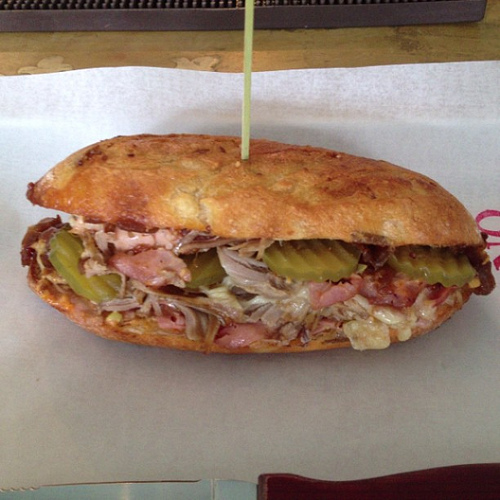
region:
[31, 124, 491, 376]
an amazing looking sandwich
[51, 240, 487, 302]
pickles are in the sandwich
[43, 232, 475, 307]
the pickles are green in color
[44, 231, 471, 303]
the pickles have crinkles in them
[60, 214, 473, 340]
meat is in the sandwich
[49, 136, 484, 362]
the bread is a golden brown color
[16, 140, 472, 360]
the bread looks toasted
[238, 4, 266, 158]
a stick in the bread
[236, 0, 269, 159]
the stick is small and skinny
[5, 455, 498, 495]
a knife near the sandwich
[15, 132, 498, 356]
a sandwich filled with meat.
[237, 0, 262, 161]
a stick sticking out of a sandwich.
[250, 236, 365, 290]
a pickle on a sandwich.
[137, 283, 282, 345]
onion on a sandwich.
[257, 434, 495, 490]
A brown wooden knife handle.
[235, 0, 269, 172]
A tooth pick in a sandwich.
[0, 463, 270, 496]
A sharp blade on a knife.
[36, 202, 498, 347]
meaty filling in a sandwich.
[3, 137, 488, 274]
the top of a sandwich.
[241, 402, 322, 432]
a section of a counter top.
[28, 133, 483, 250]
toasted bun on sandwich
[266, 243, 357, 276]
green pickle in sandwich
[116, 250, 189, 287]
cooked ham in sandwich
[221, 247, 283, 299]
pulled pork in sandwich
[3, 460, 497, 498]
wood and metal knife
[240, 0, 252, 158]
green pick in sandwich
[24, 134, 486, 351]
toasted cuban sandwich on paper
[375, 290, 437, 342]
melted cheese in sandwich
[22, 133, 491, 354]
toasted sandwich on paper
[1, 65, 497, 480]
white wax food paper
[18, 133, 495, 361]
Cold sub on a white sheet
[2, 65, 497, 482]
White sheet used to hold the sub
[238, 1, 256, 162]
Thin stick used to hold the contents of the sub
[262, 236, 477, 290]
Couple of pickles in the sub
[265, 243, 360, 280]
Pickle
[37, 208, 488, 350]
Group of cold cut meats and cheese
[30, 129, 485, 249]
Top layer of the toasted bread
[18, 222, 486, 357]
Bottom layer of the toasted bread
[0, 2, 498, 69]
Table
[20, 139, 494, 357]
Sub lying on a table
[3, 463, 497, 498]
Silver and wood knife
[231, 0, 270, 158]
Skinny mint green toothpick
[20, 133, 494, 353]
Sandwitch with pork, ham, cheese and pickles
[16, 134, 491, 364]
Lightly toasted sandwitch bun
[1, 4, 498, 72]
Light brown table with water stains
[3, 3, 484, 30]
Dark brown mat with bristles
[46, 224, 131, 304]
Circular, thin pickle slice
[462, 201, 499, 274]
Red letters on white background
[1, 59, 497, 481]
Sandwitch sitting on white paper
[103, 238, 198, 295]
Thinly sliced piece of ham